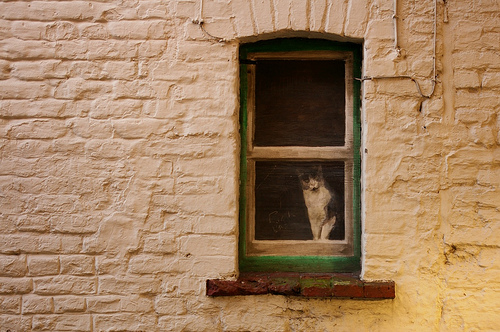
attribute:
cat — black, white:
[293, 160, 345, 238]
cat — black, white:
[301, 173, 325, 223]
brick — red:
[363, 277, 398, 302]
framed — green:
[209, 281, 359, 332]